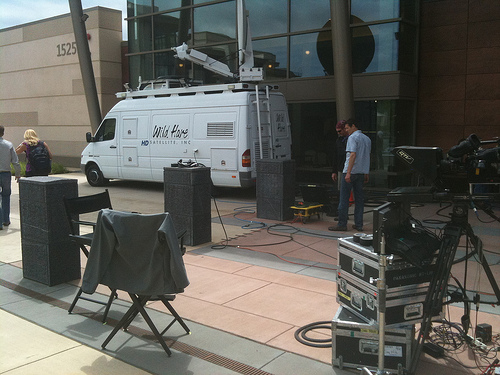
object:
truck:
[80, 73, 304, 190]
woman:
[7, 125, 53, 175]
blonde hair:
[19, 125, 47, 144]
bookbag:
[21, 143, 52, 178]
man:
[341, 118, 372, 237]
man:
[328, 116, 345, 229]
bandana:
[334, 117, 347, 132]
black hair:
[344, 116, 359, 133]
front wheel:
[80, 162, 109, 189]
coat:
[76, 192, 188, 319]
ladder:
[246, 76, 277, 159]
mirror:
[84, 130, 98, 144]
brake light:
[240, 145, 252, 171]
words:
[141, 122, 194, 148]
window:
[84, 117, 117, 150]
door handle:
[106, 142, 121, 155]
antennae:
[168, 1, 263, 86]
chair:
[89, 204, 197, 366]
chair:
[62, 184, 121, 336]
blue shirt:
[339, 131, 375, 178]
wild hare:
[152, 122, 190, 141]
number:
[50, 38, 81, 60]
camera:
[383, 129, 495, 214]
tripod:
[408, 194, 498, 370]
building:
[1, 9, 147, 185]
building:
[112, 0, 498, 197]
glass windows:
[134, 0, 400, 84]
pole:
[59, 0, 97, 137]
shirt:
[0, 137, 18, 177]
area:
[5, 3, 486, 322]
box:
[160, 154, 216, 250]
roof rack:
[112, 74, 276, 100]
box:
[250, 155, 299, 227]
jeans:
[326, 174, 370, 236]